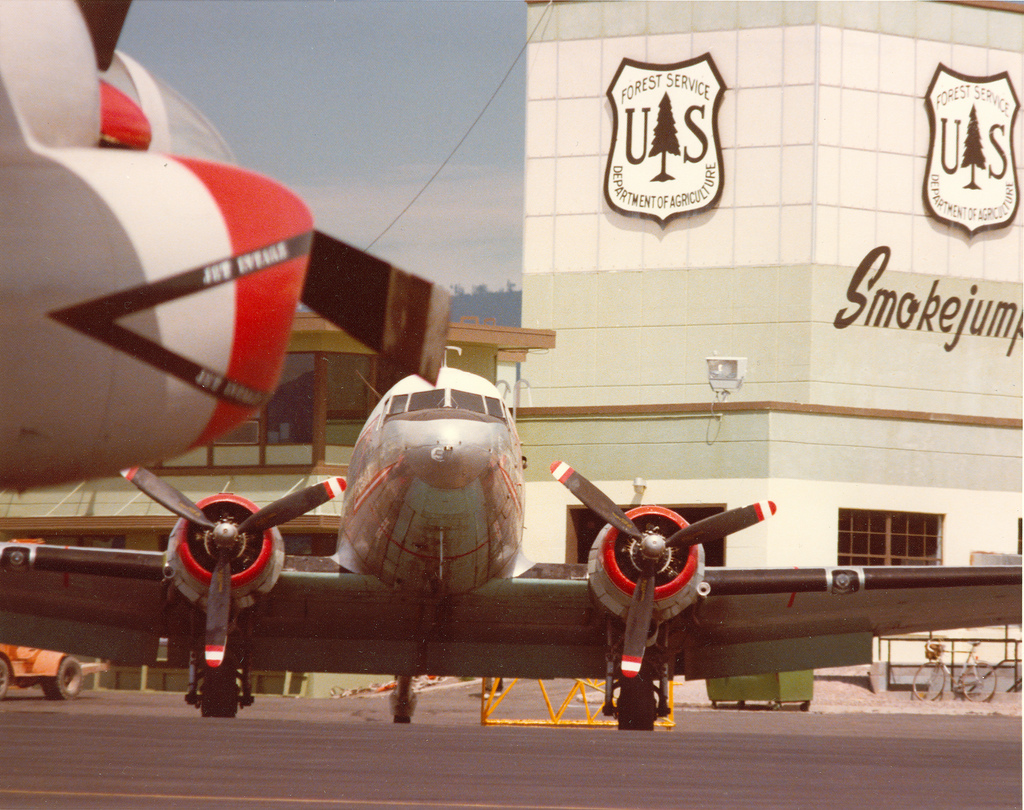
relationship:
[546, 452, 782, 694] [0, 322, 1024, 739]
engine on plane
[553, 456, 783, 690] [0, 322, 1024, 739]
propeller on plane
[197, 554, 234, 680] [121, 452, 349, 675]
blade on propellor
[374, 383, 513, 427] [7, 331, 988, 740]
windows on airplane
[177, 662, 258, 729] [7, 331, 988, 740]
wheel on airplane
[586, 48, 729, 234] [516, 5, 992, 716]
sign on building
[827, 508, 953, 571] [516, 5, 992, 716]
windows on building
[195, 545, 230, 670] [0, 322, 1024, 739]
propeller on plane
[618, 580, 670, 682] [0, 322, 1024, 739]
propeller on plane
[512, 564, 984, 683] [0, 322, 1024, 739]
wing of plane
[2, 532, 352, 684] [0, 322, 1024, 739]
wing of plane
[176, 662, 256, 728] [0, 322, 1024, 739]
wheel of plane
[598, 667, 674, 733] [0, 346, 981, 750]
wheel of plane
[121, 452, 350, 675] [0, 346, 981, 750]
propellor on plane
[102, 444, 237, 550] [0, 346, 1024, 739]
propeller on airplane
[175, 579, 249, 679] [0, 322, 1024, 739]
propeller on plane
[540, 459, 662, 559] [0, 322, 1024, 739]
propeller on plane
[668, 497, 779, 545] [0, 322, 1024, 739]
propeller on plane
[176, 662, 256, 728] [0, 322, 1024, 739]
wheel on plane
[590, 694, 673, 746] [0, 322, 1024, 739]
wheel on plane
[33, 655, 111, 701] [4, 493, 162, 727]
wheel on plane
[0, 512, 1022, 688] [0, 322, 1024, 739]
wings are on plane